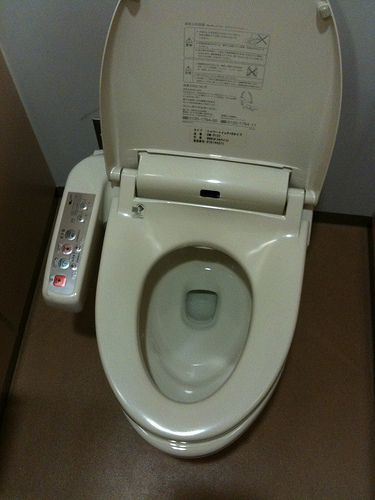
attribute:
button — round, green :
[58, 258, 67, 268]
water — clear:
[135, 240, 255, 405]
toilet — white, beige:
[40, 1, 347, 455]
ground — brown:
[50, 433, 120, 497]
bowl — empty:
[139, 244, 252, 406]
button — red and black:
[50, 273, 67, 289]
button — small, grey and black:
[76, 200, 91, 213]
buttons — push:
[56, 186, 94, 259]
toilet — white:
[88, 175, 319, 464]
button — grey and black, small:
[29, 191, 106, 291]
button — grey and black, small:
[69, 255, 82, 273]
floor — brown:
[304, 340, 367, 475]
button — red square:
[47, 272, 68, 288]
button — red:
[47, 268, 73, 290]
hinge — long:
[106, 134, 354, 256]